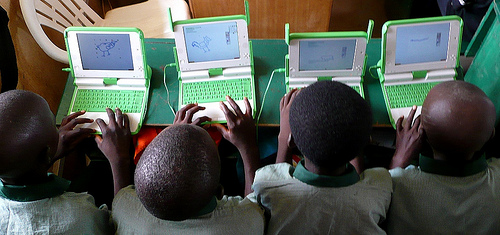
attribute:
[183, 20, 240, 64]
screen — small, white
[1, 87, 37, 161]
hair — short 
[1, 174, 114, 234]
shirt — green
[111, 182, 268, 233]
shirt — green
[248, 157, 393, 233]
shirt — green, grey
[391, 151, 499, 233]
shirt — green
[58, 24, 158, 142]
laptop — small, open, green, white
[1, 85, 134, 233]
child — black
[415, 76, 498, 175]
head — bald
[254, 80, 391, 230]
child — black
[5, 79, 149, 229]
child — black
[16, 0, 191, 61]
chair — white plastic 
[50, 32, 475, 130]
table — small green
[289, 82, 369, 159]
hair — black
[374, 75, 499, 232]
child — black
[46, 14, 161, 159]
computer — on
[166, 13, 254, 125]
laptop — green, white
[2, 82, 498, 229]
children — four, black, white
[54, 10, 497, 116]
laptops — green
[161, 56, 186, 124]
cord — white, power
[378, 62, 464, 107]
keyboard — green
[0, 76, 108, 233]
child — black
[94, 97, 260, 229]
child — black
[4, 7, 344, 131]
bench — brown